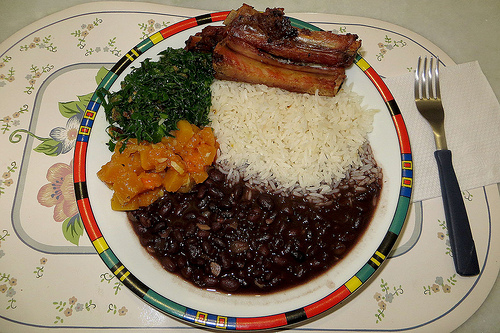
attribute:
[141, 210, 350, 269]
cooked beans — tasty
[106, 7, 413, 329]
plate — multi colored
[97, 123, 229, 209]
carrots — serving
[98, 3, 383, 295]
meal — delicious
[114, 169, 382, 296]
beans — large, brown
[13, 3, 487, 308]
tray — flower pattern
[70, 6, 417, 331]
plate — green, large, red, circle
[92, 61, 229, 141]
vegetables — healthy, nutritious, green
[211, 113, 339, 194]
rice meal — delicious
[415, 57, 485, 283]
fork — clean, metallic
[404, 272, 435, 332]
food tray — flower pattern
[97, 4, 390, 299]
food — cooked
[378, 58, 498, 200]
serviette — crisp, white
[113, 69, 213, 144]
greens — cooked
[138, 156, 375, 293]
stew — delicious, bean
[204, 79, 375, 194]
rice — white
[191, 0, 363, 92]
ribs — Spare 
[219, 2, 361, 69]
fried meat — tasty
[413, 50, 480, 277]
fork — gold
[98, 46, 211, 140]
kale — green, tasty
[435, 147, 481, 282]
handle — black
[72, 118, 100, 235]
edge — colorful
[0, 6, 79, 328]
place mat — white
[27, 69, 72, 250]
design — colorful